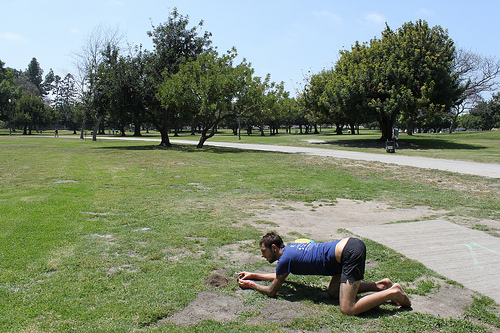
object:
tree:
[150, 50, 283, 149]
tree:
[287, 16, 481, 147]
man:
[233, 230, 416, 317]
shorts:
[337, 236, 368, 286]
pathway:
[0, 128, 500, 181]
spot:
[243, 193, 450, 245]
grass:
[0, 134, 499, 333]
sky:
[0, 1, 497, 105]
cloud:
[363, 10, 385, 27]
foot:
[389, 281, 415, 311]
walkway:
[337, 212, 500, 307]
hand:
[236, 278, 254, 291]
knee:
[336, 303, 361, 318]